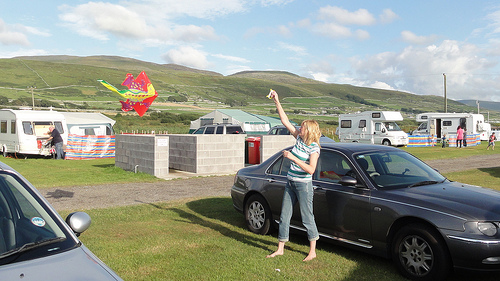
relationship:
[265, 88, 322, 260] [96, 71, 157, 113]
lady flying kite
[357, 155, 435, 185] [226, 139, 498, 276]
windshield of a car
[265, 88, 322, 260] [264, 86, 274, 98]
lady holding string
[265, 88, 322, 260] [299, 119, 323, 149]
lady with hair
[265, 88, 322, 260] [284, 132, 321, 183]
lady wearing a shirt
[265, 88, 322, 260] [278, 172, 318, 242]
lady wearing pants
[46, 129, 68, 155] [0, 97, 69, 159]
man by trailer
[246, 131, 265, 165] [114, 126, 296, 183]
bin in block structure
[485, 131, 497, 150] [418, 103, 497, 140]
people playing around trailer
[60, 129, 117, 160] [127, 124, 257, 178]
fence creating a barrier.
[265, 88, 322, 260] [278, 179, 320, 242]
lady wearing pants